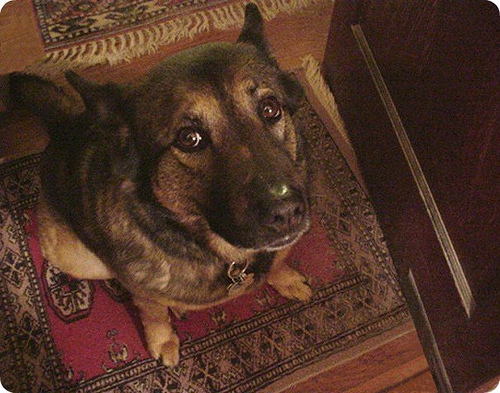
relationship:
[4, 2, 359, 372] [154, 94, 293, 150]
dog has eyes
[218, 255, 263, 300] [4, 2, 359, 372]
tags on dog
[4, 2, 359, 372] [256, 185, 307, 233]
dog has nose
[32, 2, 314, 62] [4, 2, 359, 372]
fringe behind dog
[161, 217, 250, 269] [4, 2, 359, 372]
collar on dog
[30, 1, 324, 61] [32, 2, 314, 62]
rug has fringe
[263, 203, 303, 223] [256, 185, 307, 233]
nostrils on nose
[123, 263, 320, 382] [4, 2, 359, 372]
paws on dog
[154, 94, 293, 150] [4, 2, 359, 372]
eyes on dog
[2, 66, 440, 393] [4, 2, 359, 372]
rug underneath dog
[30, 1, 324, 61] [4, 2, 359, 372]
rug behind dog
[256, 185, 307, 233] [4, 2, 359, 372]
nose on dog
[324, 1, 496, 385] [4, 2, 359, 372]
door next to dog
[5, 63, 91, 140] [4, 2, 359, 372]
tail on dog